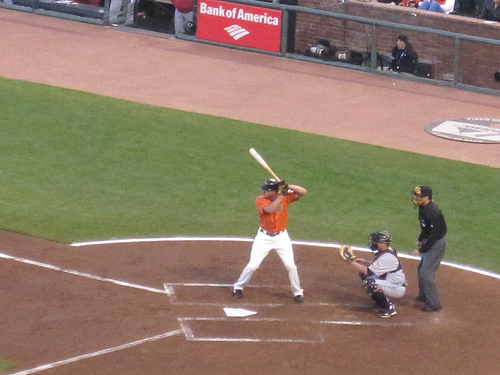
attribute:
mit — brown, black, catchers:
[336, 242, 358, 267]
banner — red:
[200, 4, 285, 54]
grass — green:
[9, 73, 495, 315]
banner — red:
[195, 0, 283, 55]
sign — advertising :
[425, 117, 498, 143]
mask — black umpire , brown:
[410, 184, 434, 211]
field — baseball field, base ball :
[0, 4, 498, 373]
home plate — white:
[218, 305, 260, 322]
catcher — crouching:
[332, 220, 417, 319]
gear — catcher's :
[329, 235, 360, 266]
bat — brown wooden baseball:
[252, 146, 284, 183]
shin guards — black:
[367, 285, 394, 315]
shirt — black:
[409, 203, 455, 257]